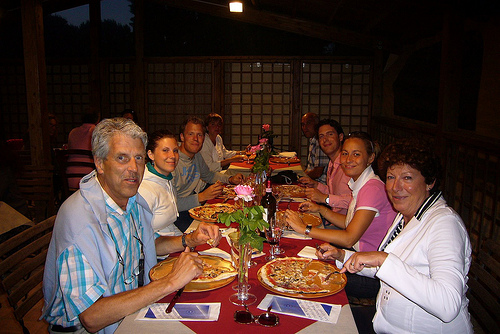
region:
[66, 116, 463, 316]
people eating individual pizzas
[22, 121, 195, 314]
man with gray hair wearing checkered shirt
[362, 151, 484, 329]
woman is smiling at camera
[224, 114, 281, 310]
flowers in vases lined up on table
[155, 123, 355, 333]
table with white and red table cloth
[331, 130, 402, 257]
person wearing pink and white outfit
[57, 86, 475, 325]
eight people eating together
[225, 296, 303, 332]
pair of sunglasses on table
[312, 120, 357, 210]
man wearing pink shirt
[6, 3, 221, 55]
picture taken at nightime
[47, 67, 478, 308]
group of people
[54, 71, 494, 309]
group of people eating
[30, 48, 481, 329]
group of people sitting at table with food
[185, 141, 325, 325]
food at a table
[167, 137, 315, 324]
pizzas on table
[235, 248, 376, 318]
fork in a pizza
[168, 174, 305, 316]
red table cloth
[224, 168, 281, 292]
small pink flower on table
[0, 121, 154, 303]
sweater around neck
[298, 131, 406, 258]
woman with pink shirt on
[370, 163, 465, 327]
She is wearing a white shirt.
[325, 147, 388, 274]
She is wearing a pink shirt.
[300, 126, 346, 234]
He is wearing a pink shirt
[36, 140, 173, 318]
He is wearing a blue shirt.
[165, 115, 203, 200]
He is wearing a grey shirt.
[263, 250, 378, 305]
She is cutting the pizza.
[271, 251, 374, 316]
She has a fork in her hand.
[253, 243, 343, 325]
The pizza is large.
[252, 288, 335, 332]
The sunglasses are on the table.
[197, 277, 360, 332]
The table cloth is red and white.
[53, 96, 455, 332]
Eight people dinning at one table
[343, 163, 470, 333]
Woman in white jacket and black and white shirt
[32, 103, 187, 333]
Man with sweater draped over shoulders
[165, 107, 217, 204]
Young man in gray sweatshirt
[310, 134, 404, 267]
A young woman in pink and white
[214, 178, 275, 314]
A flower in a vase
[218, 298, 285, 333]
Sunglasses laying on the table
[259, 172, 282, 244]
A brown beer bottle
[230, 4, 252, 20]
One light on the ceiling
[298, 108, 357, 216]
A man in a pink shirt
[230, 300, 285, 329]
A pair of sunglasses sitting on the table.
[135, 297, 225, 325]
Blue and white decorated napkin.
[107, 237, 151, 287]
Reading glasses hanging from the man's neck.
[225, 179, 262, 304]
Single pink rose sitting in a vase.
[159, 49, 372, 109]
Room separator made of wood and paper.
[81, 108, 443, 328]
Large party of people sitting together at a table.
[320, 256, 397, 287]
Fork being held in the left hand.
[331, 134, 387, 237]
Girl wearing a pink shirt.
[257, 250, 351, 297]
Large round plate of pizza.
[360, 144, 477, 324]
Woman wearing a white sweater and striped shirt.